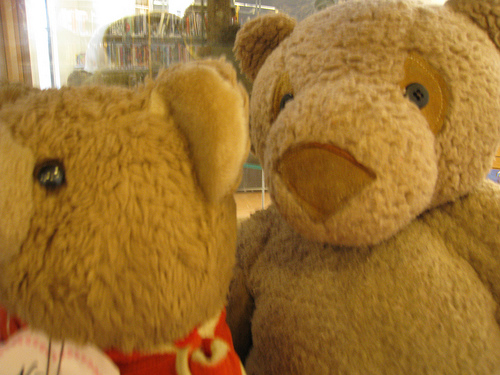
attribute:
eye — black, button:
[402, 75, 429, 112]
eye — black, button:
[277, 89, 298, 111]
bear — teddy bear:
[11, 32, 264, 337]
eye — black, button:
[390, 76, 465, 158]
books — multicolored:
[118, 9, 197, 57]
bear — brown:
[205, 2, 498, 367]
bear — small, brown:
[22, 62, 243, 373]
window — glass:
[4, 0, 344, 191]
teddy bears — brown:
[0, 0, 499, 373]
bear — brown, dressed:
[18, 37, 310, 369]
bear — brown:
[232, 9, 489, 369]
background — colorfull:
[13, 4, 263, 69]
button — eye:
[394, 53, 450, 133]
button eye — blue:
[403, 82, 428, 110]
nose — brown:
[269, 141, 378, 213]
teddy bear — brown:
[224, 2, 499, 373]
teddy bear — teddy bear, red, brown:
[0, 57, 251, 372]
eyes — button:
[371, 67, 473, 131]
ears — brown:
[242, 6, 499, 68]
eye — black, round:
[403, 80, 429, 110]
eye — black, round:
[279, 91, 295, 111]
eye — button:
[398, 77, 435, 115]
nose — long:
[278, 127, 371, 236]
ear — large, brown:
[151, 55, 249, 200]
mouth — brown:
[297, 210, 349, 248]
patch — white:
[0, 319, 129, 372]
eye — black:
[32, 150, 69, 194]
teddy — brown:
[3, 51, 252, 372]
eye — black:
[27, 145, 68, 197]